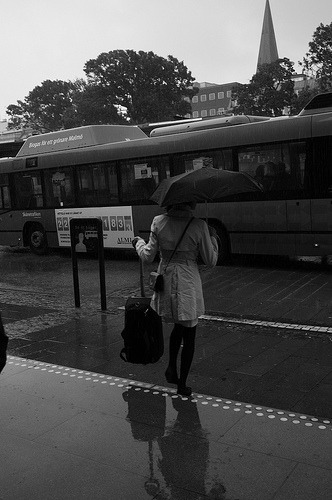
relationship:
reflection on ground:
[123, 383, 211, 499] [1, 395, 331, 498]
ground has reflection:
[1, 395, 331, 498] [123, 383, 211, 499]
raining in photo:
[1, 397, 331, 500] [1, 1, 330, 499]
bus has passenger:
[1, 93, 331, 267] [275, 158, 289, 178]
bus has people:
[1, 93, 331, 267] [262, 160, 273, 191]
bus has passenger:
[1, 93, 331, 267] [255, 163, 265, 178]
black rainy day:
[1, 137, 330, 499] [1, 2, 331, 131]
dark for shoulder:
[146, 271, 165, 294] [181, 214, 208, 237]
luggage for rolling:
[118, 296, 165, 364] [124, 358, 162, 365]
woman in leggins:
[129, 201, 221, 396] [166, 327, 196, 384]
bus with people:
[1, 93, 331, 267] [255, 160, 291, 190]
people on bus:
[255, 160, 291, 190] [1, 93, 331, 267]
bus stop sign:
[1, 93, 331, 267] [69, 217, 107, 311]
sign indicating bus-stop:
[69, 217, 107, 311] [1, 91, 330, 309]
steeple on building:
[255, 0, 279, 71] [203, 73, 306, 106]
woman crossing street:
[129, 201, 221, 396] [0, 262, 330, 417]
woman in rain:
[129, 201, 221, 396] [1, 397, 331, 500]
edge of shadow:
[143, 467, 228, 499] [121, 386, 225, 498]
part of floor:
[1, 370, 122, 499] [1, 357, 330, 499]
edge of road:
[217, 262, 331, 326] [1, 260, 329, 323]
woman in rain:
[129, 201, 221, 396] [1, 162, 331, 500]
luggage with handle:
[118, 296, 165, 364] [136, 264, 148, 297]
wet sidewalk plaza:
[1, 357, 330, 499] [1, 356, 330, 500]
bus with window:
[1, 93, 331, 267] [10, 173, 43, 209]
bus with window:
[1, 93, 331, 267] [45, 170, 73, 207]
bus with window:
[1, 93, 331, 267] [123, 164, 157, 198]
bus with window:
[1, 93, 331, 267] [238, 149, 301, 194]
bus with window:
[1, 93, 331, 267] [77, 167, 117, 205]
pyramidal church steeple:
[255, 2, 279, 60] [255, 0, 279, 71]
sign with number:
[54, 206, 133, 248] [55, 218, 63, 230]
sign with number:
[54, 206, 133, 248] [62, 218, 70, 230]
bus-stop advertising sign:
[1, 91, 330, 309] [69, 217, 107, 311]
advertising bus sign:
[70, 218, 102, 257] [69, 217, 107, 311]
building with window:
[191, 82, 235, 118] [198, 93, 206, 104]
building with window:
[191, 82, 235, 118] [207, 92, 216, 101]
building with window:
[191, 82, 235, 118] [216, 91, 225, 100]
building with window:
[191, 82, 235, 118] [199, 108, 209, 118]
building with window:
[191, 82, 235, 118] [191, 109, 199, 118]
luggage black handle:
[118, 296, 165, 364] [136, 258, 145, 294]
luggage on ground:
[118, 296, 165, 364] [1, 395, 331, 498]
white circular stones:
[254, 405, 262, 412] [244, 403, 265, 418]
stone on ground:
[215, 404, 331, 465] [1, 395, 331, 498]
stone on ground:
[29, 409, 143, 464] [1, 395, 331, 498]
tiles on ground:
[205, 268, 329, 314] [217, 262, 331, 326]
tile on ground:
[213, 335, 331, 393] [203, 332, 330, 394]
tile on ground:
[234, 358, 278, 377] [203, 332, 330, 394]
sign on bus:
[54, 206, 133, 248] [1, 93, 331, 267]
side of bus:
[1, 93, 330, 257] [1, 93, 331, 267]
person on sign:
[73, 231, 89, 252] [69, 217, 107, 311]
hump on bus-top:
[14, 113, 150, 157] [3, 93, 331, 158]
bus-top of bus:
[3, 93, 331, 158] [1, 93, 331, 267]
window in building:
[198, 93, 206, 104] [191, 82, 235, 118]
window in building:
[216, 91, 225, 100] [191, 82, 235, 118]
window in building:
[199, 108, 209, 118] [191, 82, 235, 118]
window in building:
[207, 92, 216, 101] [191, 82, 235, 118]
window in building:
[208, 106, 218, 116] [191, 82, 235, 118]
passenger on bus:
[275, 158, 289, 178] [1, 93, 331, 267]